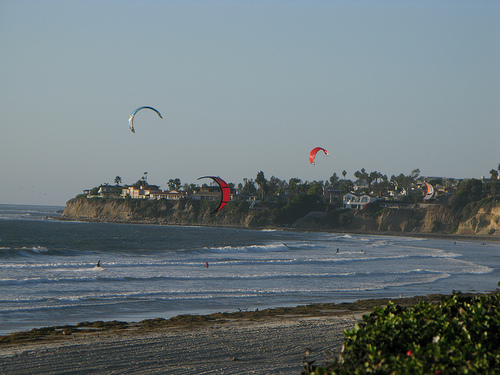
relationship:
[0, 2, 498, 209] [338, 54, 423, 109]
sky has clouds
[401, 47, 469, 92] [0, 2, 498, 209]
clouds are in sky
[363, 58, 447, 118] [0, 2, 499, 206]
clouds in blue sky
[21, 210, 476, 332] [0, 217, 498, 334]
ripples on water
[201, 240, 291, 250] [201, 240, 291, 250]
sea foam on sea foam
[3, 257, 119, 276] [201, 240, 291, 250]
sea foam on sea foam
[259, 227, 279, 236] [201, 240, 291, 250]
sea foam on sea foam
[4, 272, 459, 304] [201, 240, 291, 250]
sea foam on sea foam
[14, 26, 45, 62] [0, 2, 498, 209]
cloud in sky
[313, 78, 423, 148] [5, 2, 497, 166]
clouds in sky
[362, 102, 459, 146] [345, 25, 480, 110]
cloud in blue sky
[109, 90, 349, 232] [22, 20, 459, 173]
sails in air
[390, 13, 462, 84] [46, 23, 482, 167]
clouds in sky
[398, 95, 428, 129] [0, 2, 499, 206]
clouds in blue sky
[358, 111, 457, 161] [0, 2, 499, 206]
cloud in blue sky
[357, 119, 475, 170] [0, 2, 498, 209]
cloud in sky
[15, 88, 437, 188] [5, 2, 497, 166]
clouds in sky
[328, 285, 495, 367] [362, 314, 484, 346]
bush with leaves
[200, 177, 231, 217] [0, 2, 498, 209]
kite in sky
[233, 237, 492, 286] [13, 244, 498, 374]
waves on beach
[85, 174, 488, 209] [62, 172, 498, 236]
houses on hill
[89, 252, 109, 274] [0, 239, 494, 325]
person in water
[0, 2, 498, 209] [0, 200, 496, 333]
sky above ocean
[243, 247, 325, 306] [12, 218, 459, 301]
waves on water